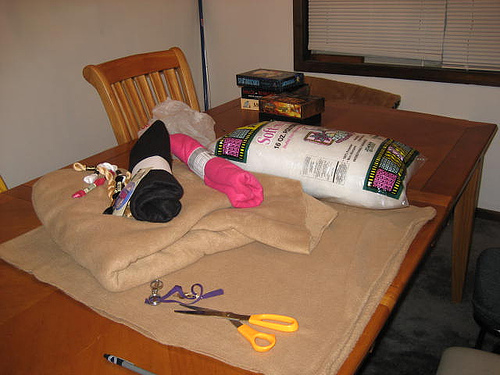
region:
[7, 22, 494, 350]
a dining room table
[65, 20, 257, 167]
a dining room table chair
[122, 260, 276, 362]
fabric scissors on the table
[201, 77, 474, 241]
a bag of batting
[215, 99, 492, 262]
a bag of stuffing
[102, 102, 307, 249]
black and pink fabric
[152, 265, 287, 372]
open pair of scissors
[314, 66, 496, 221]
a brown dining room table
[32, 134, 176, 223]
four embroidery floss colors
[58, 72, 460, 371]
fabric on a table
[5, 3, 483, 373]
a scene happening in a house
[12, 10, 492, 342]
a scene inside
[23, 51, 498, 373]
a brown table with random items on top of it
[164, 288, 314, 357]
a pair of scissors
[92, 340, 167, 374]
a ballpoint pen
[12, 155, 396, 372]
some tan blankets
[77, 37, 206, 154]
a brown chair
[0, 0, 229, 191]
a white wall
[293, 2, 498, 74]
a white curtain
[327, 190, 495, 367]
a blue carpet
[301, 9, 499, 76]
white mini blinds in window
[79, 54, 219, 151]
wooden slatted dining room chair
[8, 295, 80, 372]
light brown wooden dining room table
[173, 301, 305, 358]
pair of scissors with yellow handles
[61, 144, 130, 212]
assorted embroidery thread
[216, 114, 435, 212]
a bag of soft cotton stuffing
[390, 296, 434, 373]
grey carpet on floor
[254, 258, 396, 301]
tan fleece material on table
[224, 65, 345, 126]
boxes on wooden table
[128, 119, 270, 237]
two rolls of fleece material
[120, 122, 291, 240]
Material rolled up on table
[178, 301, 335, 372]
Scissors with orange handles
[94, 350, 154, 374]
Pen laying on the table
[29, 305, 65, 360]
Medium colored wooden table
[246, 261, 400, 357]
Beige colored fabric on table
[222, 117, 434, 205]
Bag holding cotton stuffing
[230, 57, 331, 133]
Stack of movies on the table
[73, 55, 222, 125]
Wooden chair beside table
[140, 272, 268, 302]
Purple cord on instrument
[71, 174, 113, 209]
Pink marker on table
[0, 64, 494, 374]
Scissors are on table.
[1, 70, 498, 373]
The table is rectangular.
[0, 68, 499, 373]
The table is wood.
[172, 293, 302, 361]
Scissors have yellow handle.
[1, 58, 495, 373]
Brown fabric on table.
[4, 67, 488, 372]
Pink fabric on table.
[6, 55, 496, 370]
Black fabric on table.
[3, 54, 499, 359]
Bag of stuffing on table.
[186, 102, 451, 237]
The stuffing is white.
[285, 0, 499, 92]
Mini blinds on a window.